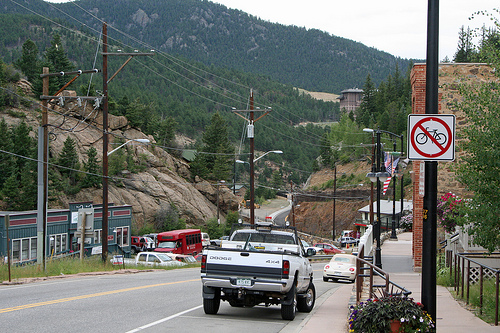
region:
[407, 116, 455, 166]
no bicycle sign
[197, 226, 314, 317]
white dodge truck parked on the side of the road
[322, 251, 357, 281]
white beetle car parked on the side of the road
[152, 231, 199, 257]
red van parked in a parking lot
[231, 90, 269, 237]
telephone pole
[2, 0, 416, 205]
tall mountain with pine trees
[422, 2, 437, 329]
a black pole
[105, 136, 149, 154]
street light hanging from telephone pole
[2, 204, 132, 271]
building on the side of the road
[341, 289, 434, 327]
pot with flowers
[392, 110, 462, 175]
black red and white sign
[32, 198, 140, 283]
green and red building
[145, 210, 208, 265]
red truck with white writing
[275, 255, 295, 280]
a red tail light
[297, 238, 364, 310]
a small white car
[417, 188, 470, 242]
pink flowers and green leaves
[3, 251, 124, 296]
grass growing on side of road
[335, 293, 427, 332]
colored flowers in a pot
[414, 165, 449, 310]
black poles with yellow writing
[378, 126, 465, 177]
red white and black sign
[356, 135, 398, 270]
black pole with white bulb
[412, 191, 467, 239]
pink and purple flowers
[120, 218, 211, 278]
red and black truck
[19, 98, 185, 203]
telephone poles and wires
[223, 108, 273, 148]
silver transformer on brown pole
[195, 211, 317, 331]
white truck on road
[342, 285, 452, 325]
flowers in a flower pot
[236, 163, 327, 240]
a road thru a valley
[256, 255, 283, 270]
silver numbers that say 4 x4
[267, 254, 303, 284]
a red tail light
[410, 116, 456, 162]
bike picture on street sign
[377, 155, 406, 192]
american flags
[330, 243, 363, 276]
convertible vw bug car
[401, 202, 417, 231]
flowers hanging on the building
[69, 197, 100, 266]
back of street signs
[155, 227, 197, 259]
bus is red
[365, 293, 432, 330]
flowers next to pole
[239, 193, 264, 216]
construction tractor is yellow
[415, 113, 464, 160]
red circle with line through bike on street sign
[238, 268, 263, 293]
license plate on the truck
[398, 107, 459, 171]
sign that prohibits bicycling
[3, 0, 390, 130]
tree-covered mountains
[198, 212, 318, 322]
white four-wheel drive pickup truck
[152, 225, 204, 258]
red bus in parking lot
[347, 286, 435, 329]
potted flowers on sidewalk by sign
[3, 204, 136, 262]
green building with red stripe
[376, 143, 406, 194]
flags hanging from pole off business building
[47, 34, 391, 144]
electrical wires and poles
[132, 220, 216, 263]
parking lot at business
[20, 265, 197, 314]
double yellow lines on road